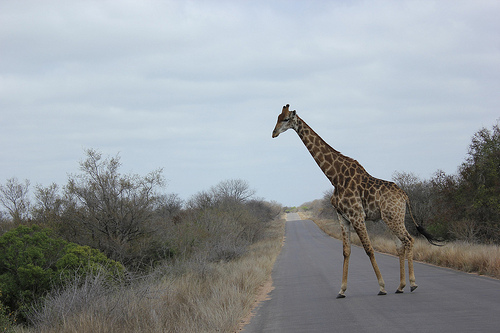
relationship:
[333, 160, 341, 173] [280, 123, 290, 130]
brown and white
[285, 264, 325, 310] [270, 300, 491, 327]
grey paved ground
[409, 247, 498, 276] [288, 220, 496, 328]
side of road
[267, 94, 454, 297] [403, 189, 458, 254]
giraffe has tail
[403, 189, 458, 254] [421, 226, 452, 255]
tail has hair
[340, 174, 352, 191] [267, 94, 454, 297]
spot on giraffe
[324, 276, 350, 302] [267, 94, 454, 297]
hoof of giraffe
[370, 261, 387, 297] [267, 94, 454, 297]
hoof of giraffe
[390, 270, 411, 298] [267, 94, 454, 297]
hoof of giraffe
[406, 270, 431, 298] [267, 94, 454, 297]
hoof of giraffe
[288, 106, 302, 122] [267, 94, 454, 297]
ear of giraffe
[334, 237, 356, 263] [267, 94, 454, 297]
knee of giraffe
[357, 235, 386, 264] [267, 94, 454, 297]
knee of giraffe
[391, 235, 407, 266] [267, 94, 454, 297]
knee of giraffe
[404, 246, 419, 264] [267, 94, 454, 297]
knee of giraffe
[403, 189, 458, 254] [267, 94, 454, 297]
tail of giraffe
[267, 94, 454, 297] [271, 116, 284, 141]
giraffe has nose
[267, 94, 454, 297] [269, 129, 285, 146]
giraffe has mouth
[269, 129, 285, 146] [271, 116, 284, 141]
mouth and nose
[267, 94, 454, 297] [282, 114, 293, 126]
giraffe has eye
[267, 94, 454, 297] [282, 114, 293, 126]
giraffe right eye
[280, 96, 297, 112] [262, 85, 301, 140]
horns on head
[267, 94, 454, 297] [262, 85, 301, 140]
giraffe has head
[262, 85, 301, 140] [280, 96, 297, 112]
head has horns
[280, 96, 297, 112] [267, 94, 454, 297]
horns on giraffe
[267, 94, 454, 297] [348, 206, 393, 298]
giraffe's front leg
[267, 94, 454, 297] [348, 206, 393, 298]
giraffe's left leg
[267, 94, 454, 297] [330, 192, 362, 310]
giraffe's front leg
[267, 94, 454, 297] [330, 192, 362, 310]
giraffe's right leg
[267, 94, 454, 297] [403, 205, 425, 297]
giraffe's back leg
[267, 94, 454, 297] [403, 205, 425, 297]
giraffe's left leg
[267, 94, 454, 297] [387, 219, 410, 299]
giraffe's back leg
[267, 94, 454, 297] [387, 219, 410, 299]
giraffe's right leg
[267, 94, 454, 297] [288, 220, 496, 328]
giraffe in road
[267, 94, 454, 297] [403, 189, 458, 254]
giraffe's hanging tail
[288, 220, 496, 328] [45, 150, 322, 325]
road through wilderness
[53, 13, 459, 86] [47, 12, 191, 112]
sky with clouds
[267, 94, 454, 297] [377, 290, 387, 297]
giraffe's four hoof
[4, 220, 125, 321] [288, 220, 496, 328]
bush beside road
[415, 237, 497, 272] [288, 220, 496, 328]
grass beside road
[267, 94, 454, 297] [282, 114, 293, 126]
giraffe's left eye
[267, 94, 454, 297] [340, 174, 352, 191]
giraffe has spot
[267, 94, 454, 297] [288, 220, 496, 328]
giraffe crossing street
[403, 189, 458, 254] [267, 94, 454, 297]
tail on giraffe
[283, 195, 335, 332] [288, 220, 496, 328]
long straight road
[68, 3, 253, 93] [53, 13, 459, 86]
overcast cloudy sky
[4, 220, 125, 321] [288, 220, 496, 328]
bushes beside road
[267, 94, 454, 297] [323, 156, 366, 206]
giraffe with markings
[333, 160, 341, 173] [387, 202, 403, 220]
brown and beige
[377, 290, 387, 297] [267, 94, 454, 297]
hoof on giraffe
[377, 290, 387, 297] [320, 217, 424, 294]
hoof on legs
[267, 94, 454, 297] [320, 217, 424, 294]
giraffe has legs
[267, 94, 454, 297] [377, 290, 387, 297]
giraffe has hoof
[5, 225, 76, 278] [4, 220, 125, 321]
green scrubby bush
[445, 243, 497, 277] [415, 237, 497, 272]
brown dry grass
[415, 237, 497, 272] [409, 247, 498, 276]
grass on side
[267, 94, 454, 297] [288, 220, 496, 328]
giraffe across road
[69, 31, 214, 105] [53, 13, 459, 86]
cloudy grey sky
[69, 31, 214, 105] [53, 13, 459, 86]
cloudy overcast sky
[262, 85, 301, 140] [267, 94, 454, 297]
head on giraffe